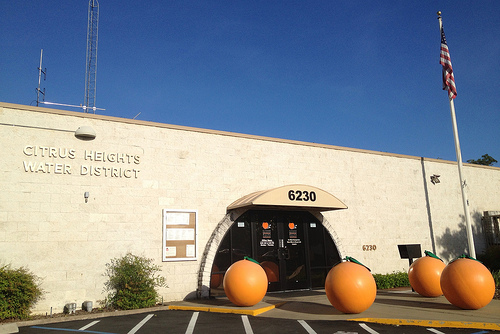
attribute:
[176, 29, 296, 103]
sky — blue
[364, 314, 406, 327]
paint — yellow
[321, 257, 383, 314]
large orange — giant, statue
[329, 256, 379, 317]
fruit — orange, giant, statue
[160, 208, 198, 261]
announcement board — small, brown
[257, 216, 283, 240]
sign — orange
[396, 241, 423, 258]
mailbox — small, black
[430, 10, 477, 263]
flag pole — tall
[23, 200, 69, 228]
paint — is white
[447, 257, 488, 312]
orange —  over sized 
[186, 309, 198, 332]
line — bold, white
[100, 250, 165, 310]
bush — green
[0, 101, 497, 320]
building — large 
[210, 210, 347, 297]
glass — large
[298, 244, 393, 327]
orange — round